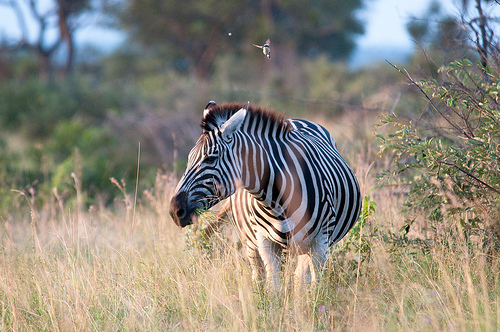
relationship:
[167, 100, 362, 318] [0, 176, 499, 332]
zebra standing in grass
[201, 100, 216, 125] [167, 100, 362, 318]
ear of a zebra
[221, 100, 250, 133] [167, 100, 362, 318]
ear of a zebra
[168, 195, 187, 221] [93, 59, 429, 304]
nose of a zebra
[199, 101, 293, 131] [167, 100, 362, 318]
hair of a zebra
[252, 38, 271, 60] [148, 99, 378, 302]
bird flying above zebra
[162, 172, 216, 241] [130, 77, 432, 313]
nose of zebra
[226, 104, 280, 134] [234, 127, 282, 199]
hair on zebra's neck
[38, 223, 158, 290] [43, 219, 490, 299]
grass in field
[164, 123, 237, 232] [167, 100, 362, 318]
face of a zebra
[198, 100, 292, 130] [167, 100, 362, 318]
mane of a zebra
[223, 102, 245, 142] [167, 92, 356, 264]
ear on a zebra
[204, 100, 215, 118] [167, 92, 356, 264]
ear on a zebra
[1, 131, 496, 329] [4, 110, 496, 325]
field of grass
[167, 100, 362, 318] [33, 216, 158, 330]
zebra eating grass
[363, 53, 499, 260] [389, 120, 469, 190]
bush with sparse leaves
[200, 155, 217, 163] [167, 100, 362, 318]
eye of zebra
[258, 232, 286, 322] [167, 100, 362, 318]
leg of zebra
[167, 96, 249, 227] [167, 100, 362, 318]
head of zebra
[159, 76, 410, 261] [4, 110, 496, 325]
zebra in grass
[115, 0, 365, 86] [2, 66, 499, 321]
tree in background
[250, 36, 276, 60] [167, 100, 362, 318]
bird above zebra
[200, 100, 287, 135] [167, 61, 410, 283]
mane of a zebra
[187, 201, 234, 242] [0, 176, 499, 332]
tail hidden by grass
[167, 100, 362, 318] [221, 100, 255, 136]
zebra has ear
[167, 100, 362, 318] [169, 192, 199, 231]
zebra has mouth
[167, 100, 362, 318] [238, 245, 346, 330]
zebra has legs